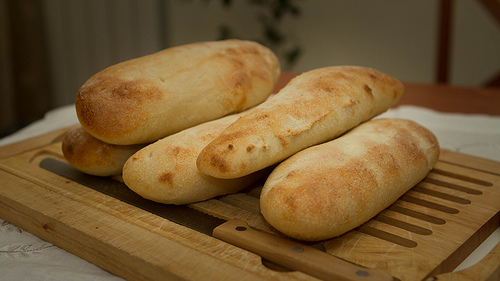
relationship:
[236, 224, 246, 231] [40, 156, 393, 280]
bolt on knife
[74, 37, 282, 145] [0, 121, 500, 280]
bread on cutting board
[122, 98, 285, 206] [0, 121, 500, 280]
bread on cutting board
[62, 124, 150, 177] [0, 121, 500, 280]
bread on cutting board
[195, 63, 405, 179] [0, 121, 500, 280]
bread on cutting board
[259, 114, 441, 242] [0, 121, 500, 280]
bread on cutting board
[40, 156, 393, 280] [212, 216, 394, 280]
knife has handle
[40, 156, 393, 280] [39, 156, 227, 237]
knife has blade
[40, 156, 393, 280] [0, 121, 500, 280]
knife in cutting board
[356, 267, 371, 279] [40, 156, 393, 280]
rivet on knife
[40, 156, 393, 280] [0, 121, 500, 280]
knife on cutting board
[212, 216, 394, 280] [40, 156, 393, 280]
handle to knife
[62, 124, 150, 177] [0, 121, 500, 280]
bread on top of cutting board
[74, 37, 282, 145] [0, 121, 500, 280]
bread on top of cutting board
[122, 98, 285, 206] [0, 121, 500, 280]
bread on top of cutting board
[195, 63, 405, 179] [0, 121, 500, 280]
bread on top of cutting board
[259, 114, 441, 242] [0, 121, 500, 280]
bread on top of cutting board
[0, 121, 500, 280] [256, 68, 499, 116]
cutting board on top of table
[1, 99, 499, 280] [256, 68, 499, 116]
table cloth on table